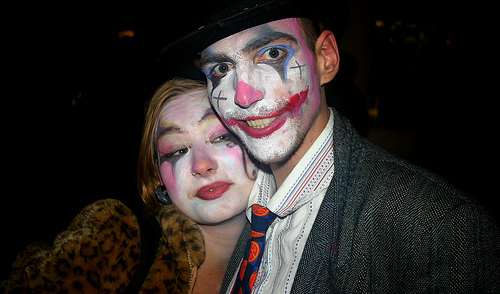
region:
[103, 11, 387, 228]
a man and a woman have their faces painted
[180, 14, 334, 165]
he appears to be painted up as a jester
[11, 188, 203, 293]
the woman wears a fur coat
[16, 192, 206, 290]
the coat is leopard print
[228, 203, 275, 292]
the man wears a necktie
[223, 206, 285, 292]
the neck tie is blue and orange in color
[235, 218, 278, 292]
oranges are on the tie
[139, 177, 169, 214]
the woman wears an earring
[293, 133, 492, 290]
the man wears a grey jacket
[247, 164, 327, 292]
the man wears a white shirt with red an blue stripes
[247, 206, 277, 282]
Blue and orange tie around man's neck.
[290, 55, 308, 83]
cross on man's face.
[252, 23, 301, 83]
Blue outline around eye.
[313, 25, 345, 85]
Right ear of clown.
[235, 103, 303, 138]
Red lipstick smeared around lips.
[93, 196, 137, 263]
Leopard fur woman's coat.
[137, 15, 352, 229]
Man and woman posing as clowns.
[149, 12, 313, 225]
White powder on couple's face.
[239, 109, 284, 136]
White teeth showing through smile.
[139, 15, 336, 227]
Woman cuddling face against man's face.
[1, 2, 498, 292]
two humans ave their faces painted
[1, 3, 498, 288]
two humans are dressed like clowns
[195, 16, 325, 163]
face is painted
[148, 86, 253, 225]
face is painted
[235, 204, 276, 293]
tie is worn around neck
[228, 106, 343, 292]
button down shirt is worn by human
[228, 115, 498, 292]
jacket is worn by human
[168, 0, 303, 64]
hat is worn by human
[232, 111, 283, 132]
mouth is open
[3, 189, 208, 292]
jacket is worn by woman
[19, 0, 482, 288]
a couple with clown faces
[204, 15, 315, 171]
white paint on a mans face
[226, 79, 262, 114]
a painted pink nose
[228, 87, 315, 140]
a red painted nose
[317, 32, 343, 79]
a mans left ear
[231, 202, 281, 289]
a blue and orange tie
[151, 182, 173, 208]
a ear ring in a ear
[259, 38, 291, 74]
a left painted eye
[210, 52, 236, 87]
a right painted eye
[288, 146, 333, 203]
a shirt with strips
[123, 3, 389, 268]
a man and a woman posing for a picture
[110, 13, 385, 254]
a man and a woman with paint on their faces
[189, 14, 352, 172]
a man with his face painted like a clown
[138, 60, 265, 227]
a woman with her face painted like a clown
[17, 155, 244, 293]
a cheetah print jacket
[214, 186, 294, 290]
a blue and orange tie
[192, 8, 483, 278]
a man in a suit jacket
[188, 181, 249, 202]
a woman's lips with lipstick